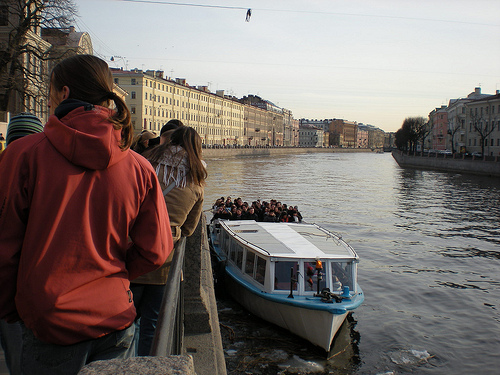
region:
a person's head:
[37, 49, 129, 116]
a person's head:
[3, 107, 38, 134]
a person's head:
[166, 123, 206, 155]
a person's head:
[151, 124, 176, 146]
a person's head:
[131, 128, 161, 153]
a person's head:
[246, 205, 256, 214]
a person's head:
[266, 209, 273, 217]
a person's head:
[236, 206, 243, 215]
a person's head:
[288, 205, 294, 210]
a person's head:
[235, 196, 246, 203]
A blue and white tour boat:
[222, 218, 354, 348]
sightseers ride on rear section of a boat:
[204, 181, 315, 262]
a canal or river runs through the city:
[217, 115, 409, 226]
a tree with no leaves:
[467, 105, 499, 163]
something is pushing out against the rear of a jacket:
[9, 95, 146, 366]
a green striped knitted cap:
[9, 91, 53, 144]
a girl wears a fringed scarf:
[147, 132, 211, 194]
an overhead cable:
[132, 0, 499, 40]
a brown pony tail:
[23, 45, 151, 152]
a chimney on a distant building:
[463, 68, 495, 108]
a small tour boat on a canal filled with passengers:
[207, 189, 392, 355]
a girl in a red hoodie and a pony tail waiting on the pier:
[10, 46, 170, 361]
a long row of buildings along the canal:
[130, 60, 363, 161]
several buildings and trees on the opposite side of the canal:
[409, 93, 495, 170]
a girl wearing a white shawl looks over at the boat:
[144, 119, 221, 228]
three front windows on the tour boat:
[275, 257, 358, 295]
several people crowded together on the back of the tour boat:
[213, 197, 305, 224]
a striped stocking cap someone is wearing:
[8, 113, 44, 139]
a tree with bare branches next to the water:
[1, 4, 80, 69]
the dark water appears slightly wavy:
[378, 187, 485, 302]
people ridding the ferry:
[204, 175, 318, 225]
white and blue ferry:
[207, 164, 372, 345]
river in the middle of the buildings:
[261, 105, 443, 329]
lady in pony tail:
[17, 45, 149, 354]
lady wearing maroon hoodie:
[9, 77, 181, 367]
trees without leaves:
[8, 0, 70, 99]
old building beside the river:
[131, 56, 361, 151]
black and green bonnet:
[3, 102, 49, 146]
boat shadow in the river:
[313, 308, 388, 355]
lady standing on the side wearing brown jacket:
[143, 115, 222, 277]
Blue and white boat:
[209, 188, 371, 362]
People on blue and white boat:
[207, 181, 381, 356]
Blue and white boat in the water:
[195, 167, 385, 362]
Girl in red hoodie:
[0, 45, 172, 374]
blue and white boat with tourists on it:
[204, 184, 371, 368]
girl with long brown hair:
[140, 110, 225, 308]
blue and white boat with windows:
[206, 183, 389, 368]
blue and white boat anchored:
[182, 172, 389, 362]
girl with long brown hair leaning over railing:
[137, 114, 234, 279]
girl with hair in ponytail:
[5, 40, 187, 367]